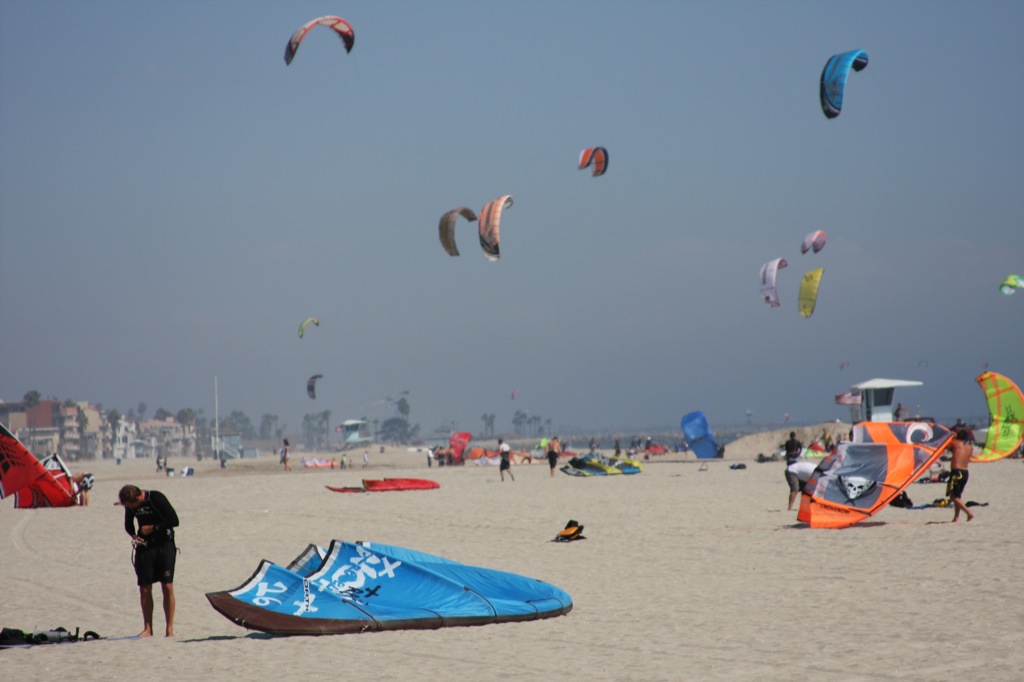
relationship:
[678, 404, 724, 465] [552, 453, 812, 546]
kite on sand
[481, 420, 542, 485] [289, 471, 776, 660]
person on beach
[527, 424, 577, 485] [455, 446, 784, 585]
person on beach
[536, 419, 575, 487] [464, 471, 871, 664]
person on beach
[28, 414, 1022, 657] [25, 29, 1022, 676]
people enjoying outdoors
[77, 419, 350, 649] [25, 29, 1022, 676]
people enjoying outdoors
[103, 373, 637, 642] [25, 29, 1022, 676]
people enjoying outdoors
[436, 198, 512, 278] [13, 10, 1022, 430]
parasail in sky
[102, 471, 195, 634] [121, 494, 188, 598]
man wears black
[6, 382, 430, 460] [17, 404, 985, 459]
buildings on horizon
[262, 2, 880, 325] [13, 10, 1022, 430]
parachutes in sky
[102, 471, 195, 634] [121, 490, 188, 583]
man wears wet suit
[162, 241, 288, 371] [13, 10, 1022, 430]
clouds in sky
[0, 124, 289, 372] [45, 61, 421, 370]
clouds in sky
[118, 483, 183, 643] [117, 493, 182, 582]
man is wearing all black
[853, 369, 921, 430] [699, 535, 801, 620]
stand on sand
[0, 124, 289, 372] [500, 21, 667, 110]
clouds in sky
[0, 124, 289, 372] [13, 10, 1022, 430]
clouds in sky